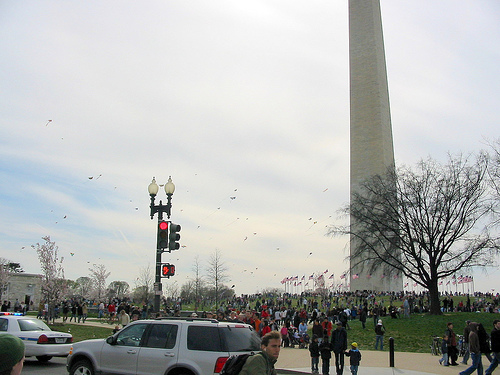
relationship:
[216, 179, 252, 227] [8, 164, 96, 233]
birds flying in sky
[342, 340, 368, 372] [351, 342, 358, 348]
boy wearing hat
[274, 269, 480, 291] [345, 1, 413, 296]
flags surrounding monument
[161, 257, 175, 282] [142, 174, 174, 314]
crosswalk sign on streetlight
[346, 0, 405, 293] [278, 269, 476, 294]
cement monument surrounded by flags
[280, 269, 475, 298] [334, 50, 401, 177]
flags surrounding monument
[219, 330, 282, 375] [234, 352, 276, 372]
man wearing parka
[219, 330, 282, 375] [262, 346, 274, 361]
man wearing earbuds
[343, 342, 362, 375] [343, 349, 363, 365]
boy in coat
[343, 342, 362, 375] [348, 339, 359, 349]
boy in hat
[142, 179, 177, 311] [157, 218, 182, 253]
lamppost with traffic lights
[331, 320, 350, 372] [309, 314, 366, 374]
adult with children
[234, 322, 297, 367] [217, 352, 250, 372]
man wearing backpack